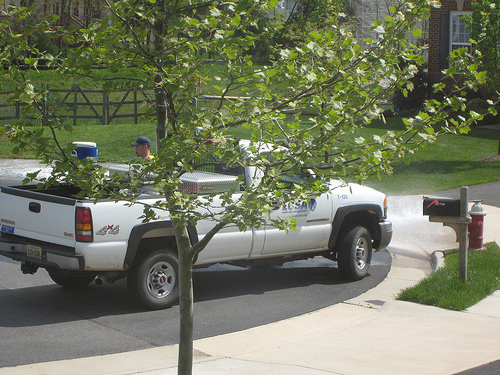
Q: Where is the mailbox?
A: Front lawn.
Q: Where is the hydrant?
A: Beside mailbox.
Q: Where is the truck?
A: On street.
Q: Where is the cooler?
A: On back of truck.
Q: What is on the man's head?
A: A hat.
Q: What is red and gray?
A: Fire hydrant.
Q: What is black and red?
A: Mailbox.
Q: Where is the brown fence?
A: On left side of grass.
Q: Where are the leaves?
A: On the tree.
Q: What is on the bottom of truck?
A: Tires.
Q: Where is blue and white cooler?
A: On leftside of truck.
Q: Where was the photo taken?
A: Residential street.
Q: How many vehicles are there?
A: One.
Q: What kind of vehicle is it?
A: Pickup truck.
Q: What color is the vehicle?
A: White.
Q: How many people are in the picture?
A: One.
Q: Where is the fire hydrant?
A: Behind the mailbox.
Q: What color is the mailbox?
A: Black.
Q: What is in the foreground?
A: Tree.